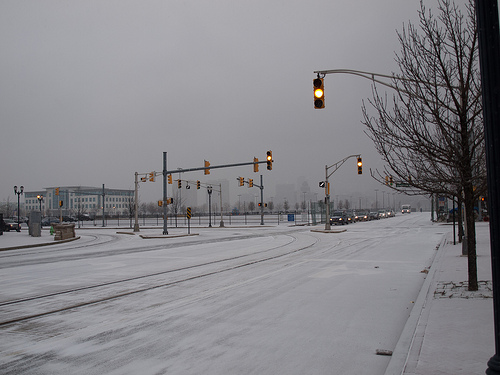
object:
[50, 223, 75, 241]
bin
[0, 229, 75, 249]
curb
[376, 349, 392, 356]
vent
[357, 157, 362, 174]
traffic light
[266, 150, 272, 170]
traffic light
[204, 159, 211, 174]
traffic light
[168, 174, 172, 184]
traffic light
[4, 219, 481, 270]
intersection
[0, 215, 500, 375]
road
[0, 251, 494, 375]
ice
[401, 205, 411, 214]
bus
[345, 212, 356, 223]
car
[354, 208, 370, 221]
car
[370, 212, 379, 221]
car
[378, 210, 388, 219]
car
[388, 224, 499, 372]
path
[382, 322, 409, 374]
edge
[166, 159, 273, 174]
board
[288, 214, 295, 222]
bin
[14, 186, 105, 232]
yellow hose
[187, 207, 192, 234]
traffic sign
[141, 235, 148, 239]
corner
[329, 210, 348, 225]
car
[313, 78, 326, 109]
light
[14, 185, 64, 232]
poles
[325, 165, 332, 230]
pole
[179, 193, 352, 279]
intersection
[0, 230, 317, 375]
tracks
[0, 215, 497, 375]
snow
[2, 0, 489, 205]
sky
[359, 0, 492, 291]
trees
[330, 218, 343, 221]
headlights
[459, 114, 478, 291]
stem